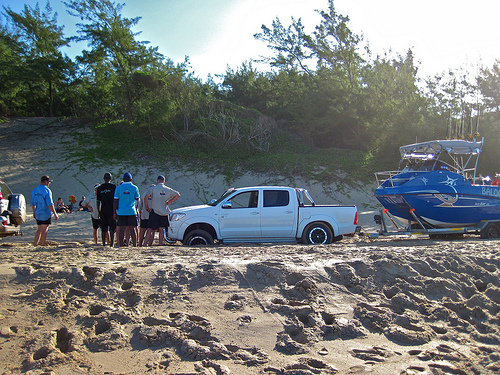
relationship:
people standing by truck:
[30, 164, 177, 252] [167, 183, 377, 258]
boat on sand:
[368, 136, 497, 226] [2, 250, 498, 371]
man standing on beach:
[112, 174, 144, 245] [0, 217, 498, 370]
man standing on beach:
[28, 177, 65, 247] [0, 217, 498, 370]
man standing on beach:
[112, 172, 140, 249] [1, 193, 491, 371]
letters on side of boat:
[462, 176, 483, 200] [363, 115, 498, 273]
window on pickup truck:
[262, 189, 289, 205] [168, 184, 358, 245]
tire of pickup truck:
[183, 228, 214, 245] [168, 184, 358, 245]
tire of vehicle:
[183, 228, 213, 245] [163, 183, 361, 247]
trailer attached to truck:
[380, 207, 499, 237] [174, 170, 325, 262]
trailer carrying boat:
[380, 207, 499, 237] [384, 160, 470, 212]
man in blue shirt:
[112, 172, 140, 249] [112, 180, 141, 216]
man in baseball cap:
[112, 172, 140, 249] [122, 171, 132, 183]